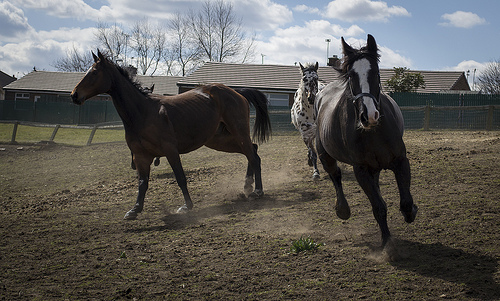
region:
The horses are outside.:
[0, 0, 498, 300]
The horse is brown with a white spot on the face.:
[310, 32, 430, 258]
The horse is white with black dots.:
[286, 56, 321, 179]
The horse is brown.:
[62, 45, 270, 226]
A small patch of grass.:
[286, 232, 321, 253]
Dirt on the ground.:
[11, 251, 262, 297]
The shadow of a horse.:
[383, 233, 498, 298]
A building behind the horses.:
[3, 66, 183, 126]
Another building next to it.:
[176, 51, 471, 122]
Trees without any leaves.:
[45, 5, 249, 70]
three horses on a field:
[35, 28, 430, 245]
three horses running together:
[51, 23, 426, 250]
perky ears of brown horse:
[81, 45, 108, 65]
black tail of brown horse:
[241, 83, 285, 129]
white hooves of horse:
[118, 205, 195, 225]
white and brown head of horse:
[335, 58, 378, 130]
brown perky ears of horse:
[335, 32, 380, 56]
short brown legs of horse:
[302, 165, 419, 242]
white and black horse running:
[290, 65, 329, 139]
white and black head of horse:
[292, 63, 326, 106]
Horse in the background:
[299, 68, 318, 108]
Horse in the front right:
[343, 53, 404, 150]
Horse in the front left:
[81, 57, 231, 150]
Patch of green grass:
[290, 232, 320, 254]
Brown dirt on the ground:
[53, 204, 243, 296]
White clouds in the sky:
[1, 0, 445, 57]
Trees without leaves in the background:
[156, 18, 246, 66]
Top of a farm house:
[423, 68, 470, 90]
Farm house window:
[17, 91, 37, 106]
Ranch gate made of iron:
[20, 120, 115, 150]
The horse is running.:
[278, 53, 344, 188]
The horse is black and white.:
[277, 48, 338, 185]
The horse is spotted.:
[286, 48, 336, 185]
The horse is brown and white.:
[309, 27, 432, 249]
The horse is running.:
[311, 27, 448, 274]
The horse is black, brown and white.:
[61, 38, 280, 227]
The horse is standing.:
[63, 42, 280, 234]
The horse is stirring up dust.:
[268, 28, 449, 283]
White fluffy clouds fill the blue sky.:
[0, 1, 499, 94]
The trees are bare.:
[36, 0, 261, 151]